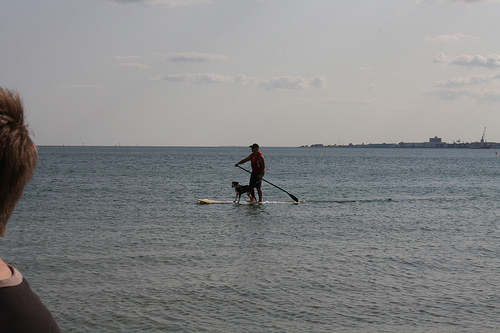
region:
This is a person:
[188, 127, 339, 252]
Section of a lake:
[77, 236, 225, 332]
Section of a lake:
[254, 257, 383, 323]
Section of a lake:
[373, 216, 481, 330]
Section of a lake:
[73, 159, 193, 289]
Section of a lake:
[332, 151, 465, 190]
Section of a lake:
[73, 146, 202, 223]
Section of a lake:
[250, 228, 466, 331]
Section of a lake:
[56, 154, 192, 309]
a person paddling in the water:
[182, 131, 357, 286]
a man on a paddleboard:
[186, 136, 358, 258]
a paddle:
[231, 159, 324, 223]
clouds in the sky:
[90, 23, 498, 120]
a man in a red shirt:
[192, 132, 335, 224]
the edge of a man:
[0, 53, 97, 324]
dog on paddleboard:
[217, 138, 279, 222]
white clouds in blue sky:
[334, 63, 378, 90]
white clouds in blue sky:
[292, 31, 344, 91]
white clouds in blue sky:
[348, 52, 396, 93]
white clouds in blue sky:
[130, 22, 182, 67]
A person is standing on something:
[95, 55, 455, 317]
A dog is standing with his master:
[92, 36, 459, 331]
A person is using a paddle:
[101, 66, 467, 317]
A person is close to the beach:
[85, 56, 480, 326]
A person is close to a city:
[93, 61, 498, 306]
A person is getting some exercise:
[93, 56, 439, 331]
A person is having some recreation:
[120, 58, 450, 330]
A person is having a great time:
[86, 25, 471, 330]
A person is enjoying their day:
[92, 53, 446, 332]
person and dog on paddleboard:
[214, 138, 294, 229]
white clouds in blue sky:
[70, 33, 121, 58]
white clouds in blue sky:
[318, 51, 332, 56]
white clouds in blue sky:
[324, 76, 366, 94]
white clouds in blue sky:
[271, 81, 299, 103]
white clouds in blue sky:
[345, 56, 379, 86]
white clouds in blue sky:
[275, 89, 300, 106]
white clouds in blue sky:
[201, 48, 249, 75]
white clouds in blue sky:
[98, 62, 179, 104]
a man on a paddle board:
[161, 103, 333, 268]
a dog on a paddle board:
[191, 131, 306, 253]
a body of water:
[199, 206, 355, 310]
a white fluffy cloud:
[256, 61, 323, 92]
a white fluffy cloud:
[168, 67, 234, 92]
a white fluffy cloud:
[118, 31, 163, 88]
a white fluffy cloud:
[424, 76, 493, 125]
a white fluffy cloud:
[440, 26, 497, 77]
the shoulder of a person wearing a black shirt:
[0, 261, 56, 332]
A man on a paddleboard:
[191, 141, 305, 208]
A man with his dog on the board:
[227, 133, 267, 208]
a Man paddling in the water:
[225, 139, 303, 214]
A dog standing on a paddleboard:
[227, 175, 260, 207]